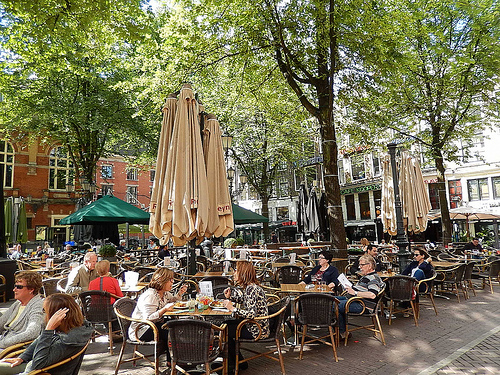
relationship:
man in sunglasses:
[0, 270, 47, 359] [8, 282, 30, 292]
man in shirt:
[335, 256, 386, 343] [345, 274, 385, 307]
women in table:
[127, 260, 274, 373] [159, 294, 236, 321]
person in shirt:
[87, 257, 124, 319] [88, 275, 122, 303]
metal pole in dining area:
[384, 138, 440, 319] [0, 227, 498, 372]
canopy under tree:
[58, 195, 151, 226] [3, 3, 161, 217]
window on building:
[2, 137, 14, 190] [1, 120, 167, 249]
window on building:
[49, 141, 78, 188] [1, 120, 167, 249]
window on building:
[98, 162, 115, 175] [1, 120, 167, 249]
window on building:
[102, 183, 114, 193] [1, 120, 167, 249]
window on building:
[124, 162, 138, 189] [1, 120, 167, 249]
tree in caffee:
[1, 2, 155, 204] [47, 193, 137, 254]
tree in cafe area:
[214, 8, 382, 235] [7, 216, 497, 372]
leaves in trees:
[83, 52, 159, 127] [1, 7, 496, 176]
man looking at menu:
[335, 256, 386, 343] [337, 272, 350, 289]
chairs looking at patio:
[120, 258, 394, 347] [307, 272, 496, 374]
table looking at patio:
[54, 215, 413, 357] [307, 272, 496, 374]